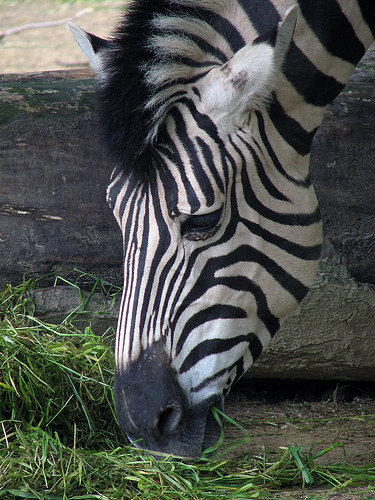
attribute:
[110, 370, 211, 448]
nose — dark, black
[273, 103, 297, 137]
stripe — black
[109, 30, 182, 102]
mane — black, white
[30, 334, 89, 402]
grass — green, light, brown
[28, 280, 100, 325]
stump — dark, grey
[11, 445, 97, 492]
ground — white, brown, light grey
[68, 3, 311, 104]
ears — white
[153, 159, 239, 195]
stripes — black, white, thick, narrow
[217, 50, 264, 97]
hair — black, white, zebra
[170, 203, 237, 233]
eyes — black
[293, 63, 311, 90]
hair — black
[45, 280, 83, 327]
rock — green, grey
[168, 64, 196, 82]
spot — white